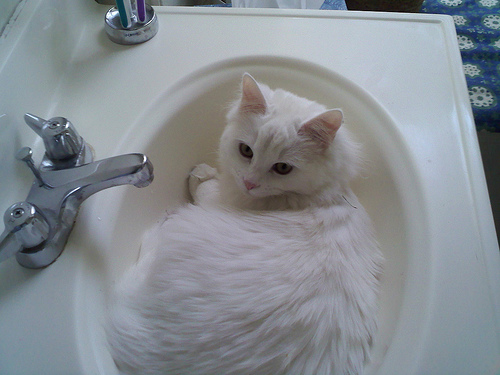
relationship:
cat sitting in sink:
[106, 66, 408, 375] [9, 6, 497, 375]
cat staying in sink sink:
[106, 66, 408, 375] [9, 6, 497, 375]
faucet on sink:
[54, 148, 158, 202] [9, 6, 497, 375]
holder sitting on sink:
[96, 4, 162, 46] [9, 6, 497, 375]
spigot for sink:
[120, 148, 159, 194] [9, 6, 497, 375]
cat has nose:
[106, 66, 408, 375] [243, 175, 261, 194]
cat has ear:
[106, 66, 408, 375] [296, 109, 342, 153]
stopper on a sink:
[8, 141, 61, 198] [9, 6, 497, 375]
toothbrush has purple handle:
[131, 0, 152, 29] [135, 2, 148, 27]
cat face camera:
[106, 66, 408, 375] [149, 349, 323, 364]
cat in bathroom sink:
[106, 66, 408, 375] [9, 6, 497, 375]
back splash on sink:
[8, 141, 61, 198] [9, 6, 497, 375]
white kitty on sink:
[106, 66, 408, 375] [9, 6, 497, 375]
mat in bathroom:
[459, 3, 495, 108] [2, 3, 500, 373]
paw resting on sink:
[181, 157, 225, 211] [9, 6, 497, 375]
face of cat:
[209, 95, 325, 210] [106, 66, 408, 375]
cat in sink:
[106, 66, 408, 375] [9, 6, 497, 375]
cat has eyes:
[106, 66, 408, 375] [236, 135, 300, 180]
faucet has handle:
[54, 148, 158, 202] [15, 103, 86, 159]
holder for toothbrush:
[96, 4, 162, 46] [131, 0, 152, 29]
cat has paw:
[106, 66, 408, 375] [181, 157, 225, 211]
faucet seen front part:
[54, 148, 158, 202] [120, 148, 159, 194]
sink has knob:
[9, 6, 497, 375] [15, 103, 86, 159]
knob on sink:
[1, 195, 59, 270] [9, 6, 497, 375]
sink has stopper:
[9, 6, 497, 375] [8, 141, 61, 198]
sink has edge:
[9, 6, 497, 375] [436, 12, 490, 220]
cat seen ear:
[106, 66, 408, 375] [296, 100, 350, 155]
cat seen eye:
[106, 66, 408, 375] [236, 135, 300, 180]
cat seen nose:
[106, 66, 408, 375] [237, 162, 266, 194]